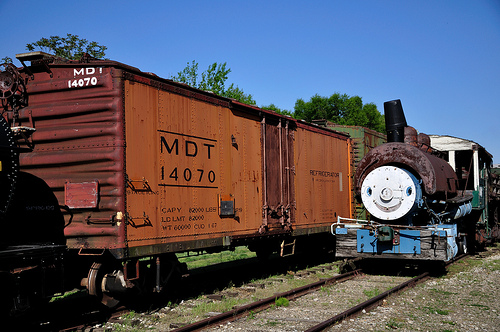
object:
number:
[71, 79, 78, 87]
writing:
[159, 205, 218, 230]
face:
[360, 164, 421, 221]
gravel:
[85, 294, 226, 330]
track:
[296, 232, 498, 329]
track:
[166, 262, 366, 330]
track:
[26, 298, 130, 329]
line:
[158, 184, 218, 188]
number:
[83, 77, 90, 86]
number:
[76, 78, 84, 86]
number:
[67, 80, 72, 88]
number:
[196, 168, 203, 182]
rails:
[178, 265, 431, 332]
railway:
[3, 43, 499, 332]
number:
[90, 77, 97, 85]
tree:
[294, 92, 394, 130]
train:
[0, 52, 391, 325]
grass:
[275, 293, 290, 309]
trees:
[25, 33, 106, 60]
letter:
[161, 135, 179, 154]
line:
[157, 129, 218, 142]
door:
[260, 117, 292, 231]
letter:
[203, 143, 215, 158]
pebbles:
[217, 314, 254, 331]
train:
[333, 99, 499, 278]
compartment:
[0, 51, 352, 259]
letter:
[185, 140, 198, 156]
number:
[169, 167, 178, 181]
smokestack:
[384, 99, 407, 143]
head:
[354, 141, 459, 223]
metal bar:
[337, 216, 378, 224]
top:
[32, 53, 350, 140]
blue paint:
[355, 228, 421, 253]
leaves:
[334, 107, 368, 127]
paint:
[370, 169, 403, 184]